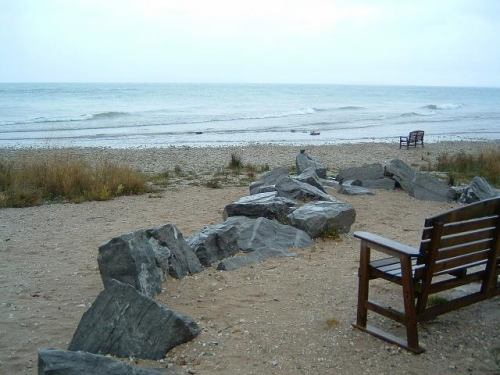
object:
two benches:
[349, 129, 499, 355]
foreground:
[0, 174, 499, 374]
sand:
[0, 141, 499, 374]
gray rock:
[93, 231, 164, 299]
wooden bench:
[349, 195, 499, 354]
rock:
[65, 277, 203, 361]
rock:
[146, 222, 206, 279]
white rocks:
[74, 301, 89, 309]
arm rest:
[351, 231, 419, 258]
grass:
[428, 148, 499, 187]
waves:
[82, 104, 317, 123]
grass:
[0, 145, 152, 209]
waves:
[419, 101, 467, 114]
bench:
[0, 140, 499, 374]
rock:
[34, 347, 169, 374]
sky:
[0, 0, 499, 88]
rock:
[221, 192, 293, 227]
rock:
[407, 169, 459, 204]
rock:
[215, 215, 314, 270]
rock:
[455, 175, 499, 204]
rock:
[247, 166, 291, 196]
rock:
[285, 201, 355, 240]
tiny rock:
[215, 286, 223, 291]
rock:
[284, 183, 339, 204]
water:
[0, 82, 499, 149]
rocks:
[381, 157, 415, 194]